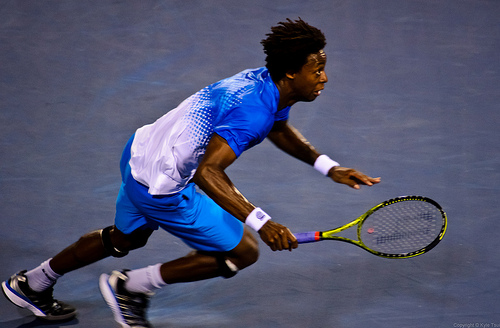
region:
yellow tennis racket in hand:
[275, 193, 449, 263]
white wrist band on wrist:
[246, 205, 271, 230]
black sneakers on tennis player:
[1, 270, 79, 325]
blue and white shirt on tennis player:
[116, 63, 283, 196]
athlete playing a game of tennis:
[3, 19, 449, 321]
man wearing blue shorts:
[6, 18, 379, 321]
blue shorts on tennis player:
[110, 139, 245, 281]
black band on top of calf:
[100, 225, 127, 258]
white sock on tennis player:
[17, 256, 59, 298]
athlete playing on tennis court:
[4, 18, 450, 321]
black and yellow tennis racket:
[323, 195, 453, 266]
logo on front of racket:
[363, 204, 433, 241]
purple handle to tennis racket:
[289, 229, 316, 246]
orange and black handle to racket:
[310, 228, 323, 244]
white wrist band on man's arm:
[248, 202, 276, 233]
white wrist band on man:
[302, 152, 339, 186]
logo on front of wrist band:
[252, 210, 269, 222]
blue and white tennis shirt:
[167, 70, 287, 171]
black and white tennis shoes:
[0, 278, 70, 318]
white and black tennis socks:
[19, 248, 68, 288]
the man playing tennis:
[0, 15, 447, 326]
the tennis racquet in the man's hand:
[260, 195, 446, 257]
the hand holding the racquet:
[261, 220, 300, 251]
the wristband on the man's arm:
[245, 206, 271, 228]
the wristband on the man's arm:
[312, 152, 339, 176]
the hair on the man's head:
[260, 15, 325, 77]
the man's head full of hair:
[260, 18, 327, 103]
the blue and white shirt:
[127, 63, 289, 195]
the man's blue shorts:
[112, 131, 244, 251]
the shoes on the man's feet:
[1, 268, 152, 326]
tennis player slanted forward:
[2, 12, 448, 317]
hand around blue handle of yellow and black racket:
[261, 192, 448, 257]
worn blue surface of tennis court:
[6, 5, 493, 320]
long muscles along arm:
[191, 130, 261, 216]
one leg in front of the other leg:
[0, 182, 260, 317]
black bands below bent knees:
[86, 181, 256, 286]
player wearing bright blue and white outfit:
[107, 60, 287, 255]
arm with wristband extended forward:
[280, 117, 380, 187]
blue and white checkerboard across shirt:
[181, 86, 211, 148]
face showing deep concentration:
[298, 27, 328, 107]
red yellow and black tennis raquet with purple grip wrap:
[293, 194, 447, 259]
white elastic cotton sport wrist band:
[313, 153, 338, 176]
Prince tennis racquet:
[291, 194, 447, 260]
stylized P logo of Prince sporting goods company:
[375, 211, 431, 241]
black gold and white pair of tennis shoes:
[2, 269, 153, 327]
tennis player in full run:
[3, 20, 497, 325]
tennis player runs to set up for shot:
[0, 17, 448, 325]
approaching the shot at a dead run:
[0, 18, 445, 325]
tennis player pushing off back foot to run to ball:
[2, 22, 445, 323]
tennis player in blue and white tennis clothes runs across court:
[0, 0, 498, 325]